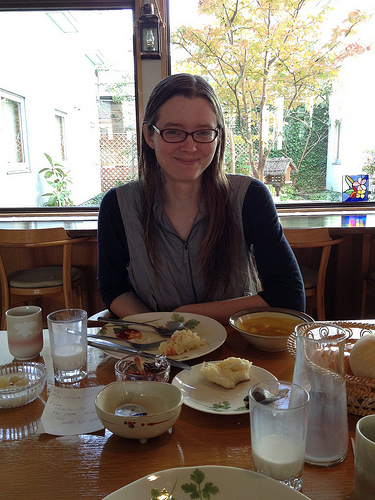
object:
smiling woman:
[97, 72, 307, 318]